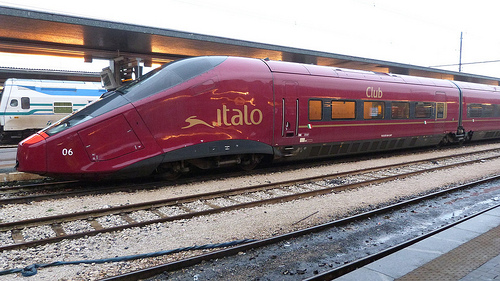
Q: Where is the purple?
A: On train.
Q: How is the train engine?
A: Red.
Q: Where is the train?
A: On tracks.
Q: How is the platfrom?
A: Empty.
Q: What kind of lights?
A: Ceiling.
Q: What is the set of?
A: Tracks.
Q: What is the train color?
A: Red.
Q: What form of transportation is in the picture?
A: Train.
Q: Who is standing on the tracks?
A: No one.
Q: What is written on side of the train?
A: Italo.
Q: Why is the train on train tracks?
A: To move.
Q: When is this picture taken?
A: Daytime.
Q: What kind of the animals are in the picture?
A: None.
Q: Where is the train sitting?
A: On the tracks.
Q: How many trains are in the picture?
A: Two.